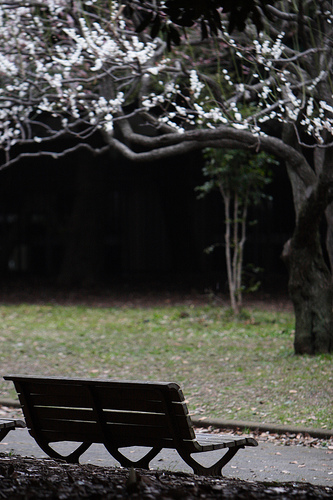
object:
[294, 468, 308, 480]
asphalt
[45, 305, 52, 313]
grass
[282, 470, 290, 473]
fallen leaves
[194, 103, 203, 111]
blossoms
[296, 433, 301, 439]
leaves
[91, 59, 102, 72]
flowers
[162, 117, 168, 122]
blooms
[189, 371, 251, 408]
ground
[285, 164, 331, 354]
trunk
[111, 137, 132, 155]
branches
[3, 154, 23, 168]
branch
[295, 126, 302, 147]
branch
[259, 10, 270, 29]
branch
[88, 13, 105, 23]
branch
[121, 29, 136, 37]
branch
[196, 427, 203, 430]
leaves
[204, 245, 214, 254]
leaves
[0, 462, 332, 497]
sidewalk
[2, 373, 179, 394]
slat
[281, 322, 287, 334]
green grass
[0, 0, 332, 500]
park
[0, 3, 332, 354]
tree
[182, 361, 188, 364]
leaves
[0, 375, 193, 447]
back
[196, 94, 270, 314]
tree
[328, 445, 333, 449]
leaves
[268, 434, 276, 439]
leaves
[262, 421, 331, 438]
curb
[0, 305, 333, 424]
grassy area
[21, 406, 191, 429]
slat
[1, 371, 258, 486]
bench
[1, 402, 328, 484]
path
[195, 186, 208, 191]
leaves